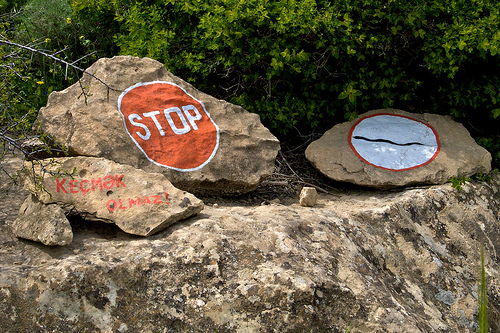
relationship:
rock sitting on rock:
[300, 187, 319, 207] [2, 185, 498, 331]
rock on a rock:
[300, 187, 319, 207] [0, 162, 496, 331]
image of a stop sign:
[353, 130, 424, 150] [117, 81, 221, 172]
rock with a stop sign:
[32, 55, 281, 199] [115, 76, 222, 178]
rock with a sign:
[304, 108, 492, 186] [350, 111, 439, 174]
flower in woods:
[34, 77, 43, 84] [0, 0, 499, 165]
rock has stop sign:
[10, 42, 296, 192] [115, 76, 222, 178]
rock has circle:
[304, 108, 492, 186] [347, 110, 439, 172]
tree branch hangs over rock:
[0, 39, 109, 90] [24, 156, 205, 237]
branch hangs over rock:
[2, 122, 65, 186] [11, 193, 73, 245]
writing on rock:
[49, 175, 174, 217] [4, 151, 209, 239]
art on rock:
[348, 113, 440, 170] [304, 111, 491, 201]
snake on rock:
[352, 135, 428, 147] [24, 156, 205, 237]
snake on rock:
[352, 135, 428, 147] [37, 54, 279, 194]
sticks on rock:
[258, 154, 332, 215] [86, 222, 482, 331]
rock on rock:
[300, 187, 319, 207] [49, 211, 497, 323]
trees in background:
[7, 0, 497, 140] [9, 10, 486, 235]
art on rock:
[348, 113, 440, 170] [304, 108, 492, 186]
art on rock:
[117, 81, 220, 172] [32, 55, 281, 199]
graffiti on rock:
[53, 172, 169, 215] [24, 156, 205, 237]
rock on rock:
[298, 96, 495, 198] [37, 54, 279, 194]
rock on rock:
[287, 177, 321, 204] [4, 151, 209, 239]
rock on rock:
[4, 151, 209, 239] [10, 192, 80, 249]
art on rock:
[348, 113, 440, 170] [298, 96, 495, 198]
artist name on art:
[57, 177, 173, 212] [348, 113, 440, 166]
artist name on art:
[57, 177, 173, 212] [122, 81, 218, 168]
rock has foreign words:
[24, 156, 205, 237] [47, 169, 162, 215]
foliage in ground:
[206, 2, 436, 79] [337, 185, 356, 216]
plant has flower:
[4, 18, 110, 140] [37, 81, 45, 84]